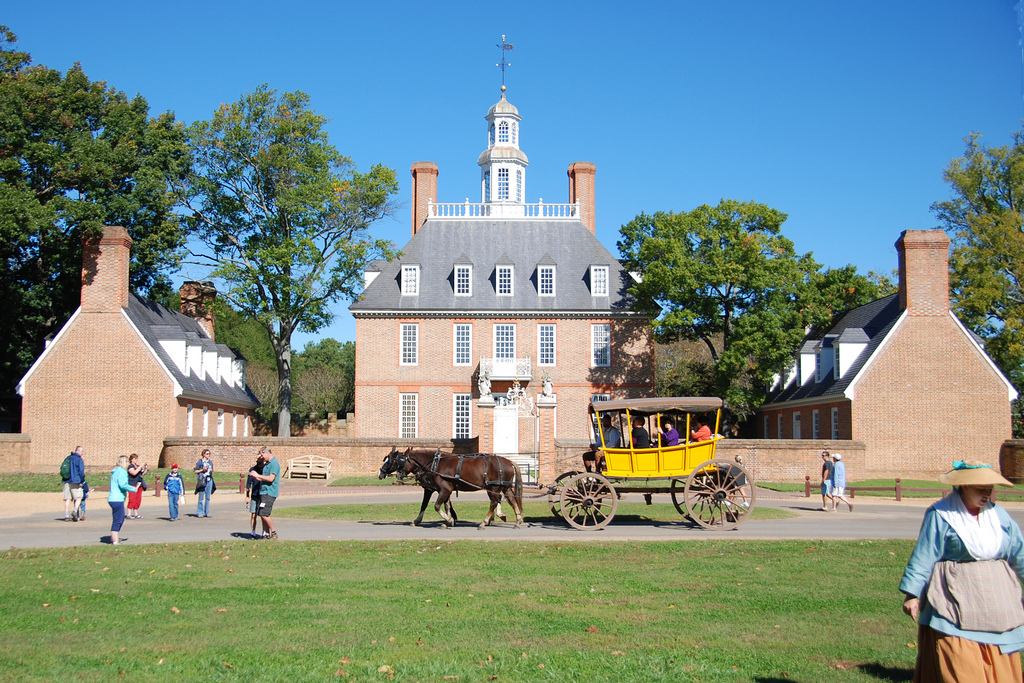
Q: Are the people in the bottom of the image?
A: Yes, the people are in the bottom of the image.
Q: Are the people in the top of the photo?
A: No, the people are in the bottom of the image.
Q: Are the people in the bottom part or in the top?
A: The people are in the bottom of the image.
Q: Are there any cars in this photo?
A: No, there are no cars.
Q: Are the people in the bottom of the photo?
A: Yes, the people are in the bottom of the image.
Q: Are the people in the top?
A: No, the people are in the bottom of the image.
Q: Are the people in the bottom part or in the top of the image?
A: The people are in the bottom of the image.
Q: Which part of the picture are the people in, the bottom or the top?
A: The people are in the bottom of the image.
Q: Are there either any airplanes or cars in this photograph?
A: No, there are no cars or airplanes.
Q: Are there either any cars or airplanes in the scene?
A: No, there are no cars or airplanes.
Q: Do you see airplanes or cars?
A: No, there are no cars or airplanes.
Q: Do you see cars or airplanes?
A: No, there are no cars or airplanes.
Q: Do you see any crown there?
A: No, there are no crowns.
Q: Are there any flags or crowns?
A: No, there are no crowns or flags.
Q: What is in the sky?
A: The clouds are in the sky.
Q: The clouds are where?
A: The clouds are in the sky.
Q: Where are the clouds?
A: The clouds are in the sky.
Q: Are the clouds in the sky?
A: Yes, the clouds are in the sky.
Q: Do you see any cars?
A: No, there are no cars.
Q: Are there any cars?
A: No, there are no cars.